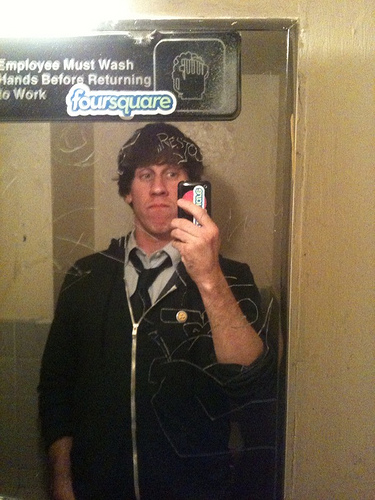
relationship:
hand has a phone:
[164, 201, 225, 265] [174, 178, 209, 236]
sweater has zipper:
[30, 215, 268, 487] [115, 253, 169, 498]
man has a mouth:
[25, 129, 277, 500] [178, 219, 179, 220]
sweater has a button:
[30, 215, 268, 487] [176, 310, 188, 323]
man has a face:
[25, 129, 277, 500] [125, 152, 191, 244]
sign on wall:
[3, 34, 244, 128] [3, 13, 370, 497]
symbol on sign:
[154, 32, 228, 106] [3, 34, 244, 128]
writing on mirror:
[16, 98, 295, 471] [6, 20, 276, 498]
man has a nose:
[25, 129, 277, 500] [148, 168, 171, 197]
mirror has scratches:
[6, 20, 276, 498] [53, 127, 293, 439]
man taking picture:
[25, 129, 277, 500] [5, 6, 374, 483]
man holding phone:
[25, 129, 277, 500] [174, 178, 209, 236]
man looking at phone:
[25, 129, 277, 500] [174, 178, 209, 236]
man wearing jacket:
[25, 129, 277, 500] [30, 200, 265, 492]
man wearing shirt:
[25, 129, 277, 500] [121, 233, 176, 316]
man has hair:
[25, 129, 277, 500] [113, 125, 206, 199]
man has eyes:
[25, 129, 277, 500] [137, 169, 183, 187]